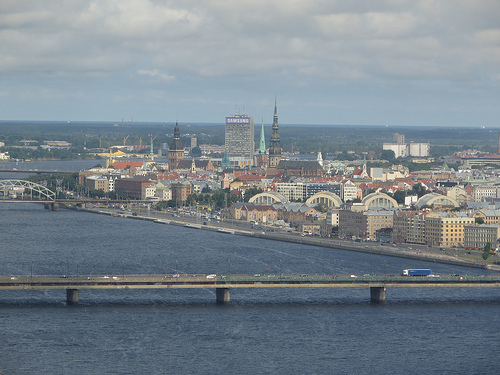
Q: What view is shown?
A: Cityscape.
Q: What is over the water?
A: Two bridges.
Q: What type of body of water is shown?
A: River.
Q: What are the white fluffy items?
A: Clouds.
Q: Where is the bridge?
A: Over the water.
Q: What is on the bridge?
A: Vehicles.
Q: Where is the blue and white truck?
A: On the bridge.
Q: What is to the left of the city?
A: Water.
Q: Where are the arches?
A: On top of the buildings.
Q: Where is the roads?
A: The right of the water.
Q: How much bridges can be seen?
A: Three.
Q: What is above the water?
A: A bridge.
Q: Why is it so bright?
A: Sunny.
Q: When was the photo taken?
A: Day time.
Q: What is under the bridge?
A: Water.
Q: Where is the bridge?
A: Middle of the water.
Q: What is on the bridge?
A: Cars.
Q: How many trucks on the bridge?
A: One.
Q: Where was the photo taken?
A: From a distance.